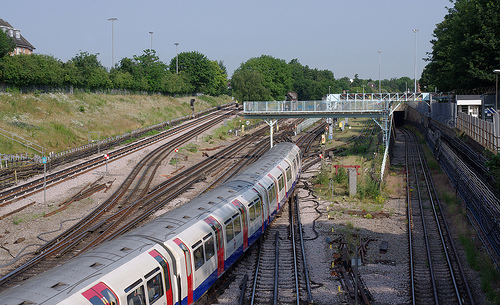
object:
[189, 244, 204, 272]
window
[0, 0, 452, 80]
sky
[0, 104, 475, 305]
train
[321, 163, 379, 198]
green vegetation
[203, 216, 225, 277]
door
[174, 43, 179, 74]
pole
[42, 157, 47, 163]
sign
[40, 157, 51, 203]
post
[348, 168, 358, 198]
pole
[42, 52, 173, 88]
trees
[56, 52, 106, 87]
green leaves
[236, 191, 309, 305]
track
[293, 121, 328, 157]
track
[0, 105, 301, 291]
track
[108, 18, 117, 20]
street light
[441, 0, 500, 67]
green tree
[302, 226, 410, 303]
rocks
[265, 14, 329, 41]
white clouds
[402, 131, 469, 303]
track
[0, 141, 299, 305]
tain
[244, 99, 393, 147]
bridge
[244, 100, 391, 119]
overpass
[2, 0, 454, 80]
blue sky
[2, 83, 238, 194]
hill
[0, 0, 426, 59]
clouds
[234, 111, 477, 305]
tracks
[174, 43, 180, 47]
light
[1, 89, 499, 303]
ground